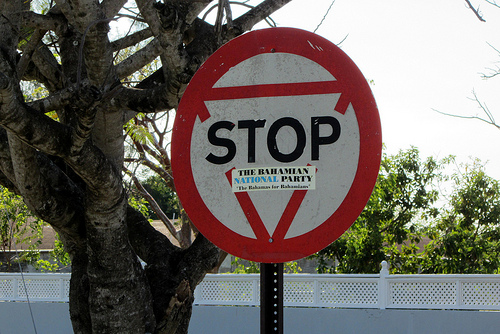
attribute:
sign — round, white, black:
[164, 25, 390, 268]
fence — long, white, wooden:
[1, 270, 500, 315]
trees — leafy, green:
[0, 0, 499, 275]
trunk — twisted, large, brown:
[1, 1, 353, 332]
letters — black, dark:
[203, 114, 343, 164]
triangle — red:
[195, 82, 360, 239]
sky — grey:
[18, 0, 499, 235]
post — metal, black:
[257, 261, 286, 333]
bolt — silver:
[268, 236, 276, 246]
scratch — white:
[305, 38, 326, 54]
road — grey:
[2, 302, 499, 334]